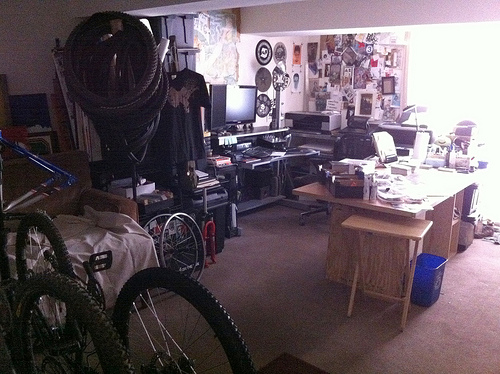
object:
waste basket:
[407, 251, 449, 308]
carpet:
[137, 207, 497, 369]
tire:
[14, 220, 69, 265]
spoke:
[14, 295, 55, 345]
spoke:
[22, 235, 66, 267]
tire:
[147, 207, 207, 269]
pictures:
[254, 38, 276, 66]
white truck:
[0, 205, 161, 298]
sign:
[269, 40, 289, 63]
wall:
[238, 34, 406, 124]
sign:
[307, 42, 318, 63]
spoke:
[129, 285, 191, 372]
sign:
[255, 93, 272, 118]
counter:
[291, 143, 483, 304]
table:
[290, 159, 487, 302]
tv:
[210, 84, 257, 128]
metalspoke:
[31, 297, 98, 370]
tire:
[13, 272, 133, 372]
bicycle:
[0, 266, 137, 373]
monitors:
[208, 85, 260, 124]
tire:
[97, 255, 257, 372]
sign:
[272, 70, 287, 91]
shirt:
[158, 64, 213, 166]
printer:
[280, 108, 342, 132]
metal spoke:
[131, 297, 167, 365]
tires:
[107, 269, 265, 369]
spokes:
[53, 300, 195, 365]